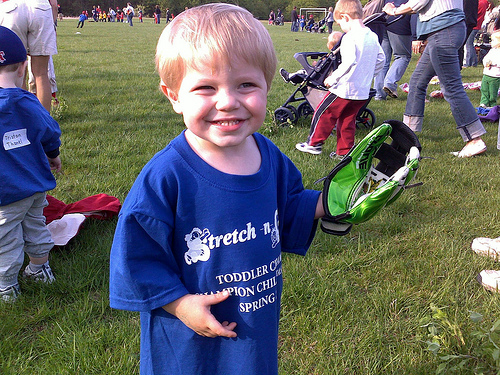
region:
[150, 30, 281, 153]
A young boy smiling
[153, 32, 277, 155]
A young boy with blonde hair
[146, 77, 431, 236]
Young boy with a baseball mitt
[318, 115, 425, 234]
Baseball mitt is green black and white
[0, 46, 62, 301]
A very small ball player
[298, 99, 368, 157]
A small pair of red jogging pants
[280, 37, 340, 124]
A stroller with a young child in it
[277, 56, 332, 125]
The stroller is black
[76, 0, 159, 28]
Children playing sports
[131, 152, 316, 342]
A blue shirt with white lettering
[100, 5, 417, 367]
a little boy holding a catcher's mitt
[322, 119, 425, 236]
the mitt is green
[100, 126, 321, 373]
the shirt is blue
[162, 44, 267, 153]
the boy is smiling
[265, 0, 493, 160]
a woman pushing a stroller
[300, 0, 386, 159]
a boy beside the stroller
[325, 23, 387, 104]
his shirt is white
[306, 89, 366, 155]
his pants are red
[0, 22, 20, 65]
this boy is wearing a baseball cap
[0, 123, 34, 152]
a nametag on the back of his shirt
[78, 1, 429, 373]
little boy holding a mitt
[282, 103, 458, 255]
the mitt is green and black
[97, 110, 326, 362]
boy's shirt is blue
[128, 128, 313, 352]
white letters on shirt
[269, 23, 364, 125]
the stroller is black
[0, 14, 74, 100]
little boy wearing a hat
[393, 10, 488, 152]
woman's pants are black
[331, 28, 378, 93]
boy's shirt is white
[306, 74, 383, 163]
boy's pants are red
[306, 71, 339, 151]
black stripe on pants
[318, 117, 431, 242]
a green and black baseball glove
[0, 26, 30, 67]
part of a boy's baseball cap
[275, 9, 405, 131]
a large baby stroller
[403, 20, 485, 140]
a woman's jean pants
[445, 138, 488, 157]
a woman's white tennis shoe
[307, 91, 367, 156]
a boy's red and blue pants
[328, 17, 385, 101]
a boy's white shirt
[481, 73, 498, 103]
a child's green pants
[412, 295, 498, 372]
a green tree leaf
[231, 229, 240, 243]
a white letter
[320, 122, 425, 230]
Green and black baseball mitt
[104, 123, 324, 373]
Blue shirt on child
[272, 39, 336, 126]
Black stroller being pushed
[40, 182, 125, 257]
Red sweatshirt on ground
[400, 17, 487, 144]
Jeans person is wearing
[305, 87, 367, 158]
Red and black pants on child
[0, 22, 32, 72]
Blue hat on child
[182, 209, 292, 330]
White writing on child's shirt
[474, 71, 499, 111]
Green pants on child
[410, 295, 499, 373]
Leafy green plant on grass